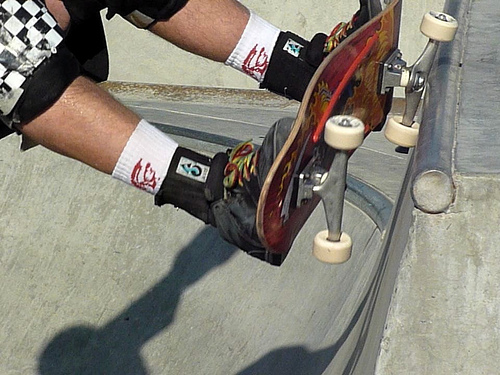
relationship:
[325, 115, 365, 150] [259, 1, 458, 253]
wheel under skateboard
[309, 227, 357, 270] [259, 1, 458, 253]
wheel under skateboard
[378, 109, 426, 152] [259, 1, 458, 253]
wheel under skateboard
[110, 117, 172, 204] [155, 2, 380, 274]
socks on man's feet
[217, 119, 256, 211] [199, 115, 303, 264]
shoelaces on shoe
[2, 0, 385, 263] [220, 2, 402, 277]
man wearing shoes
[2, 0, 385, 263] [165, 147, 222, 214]
man wearing braces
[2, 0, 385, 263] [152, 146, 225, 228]
man wearing ankle brace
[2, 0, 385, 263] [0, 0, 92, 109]
man wearing kneepad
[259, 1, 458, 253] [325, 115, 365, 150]
skateboard with wheel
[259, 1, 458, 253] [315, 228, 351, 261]
skateboard with wheel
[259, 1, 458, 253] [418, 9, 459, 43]
skateboard with wheel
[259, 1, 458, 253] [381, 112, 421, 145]
skateboard with wheel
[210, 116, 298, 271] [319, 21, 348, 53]
shoe with laces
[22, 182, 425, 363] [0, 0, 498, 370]
pavement in skatepark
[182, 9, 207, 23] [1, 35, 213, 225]
hair on leg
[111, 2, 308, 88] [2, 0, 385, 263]
leg on man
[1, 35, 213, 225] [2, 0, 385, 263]
leg on man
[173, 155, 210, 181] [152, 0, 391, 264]
logo on shoes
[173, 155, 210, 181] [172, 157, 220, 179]
logo an arrow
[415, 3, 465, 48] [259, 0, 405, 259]
wheel on skateboard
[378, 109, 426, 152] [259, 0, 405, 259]
wheel on skateboard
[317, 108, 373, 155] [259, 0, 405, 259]
wheel on skateboard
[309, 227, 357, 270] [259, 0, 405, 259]
wheel on skateboard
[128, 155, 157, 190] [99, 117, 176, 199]
design on sock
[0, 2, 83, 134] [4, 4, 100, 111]
kneepad on knee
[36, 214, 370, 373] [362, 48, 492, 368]
shadow on wall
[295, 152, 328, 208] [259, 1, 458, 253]
silver bolt under skateboard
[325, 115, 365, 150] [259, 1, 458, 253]
wheel of skateboard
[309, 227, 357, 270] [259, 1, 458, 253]
wheel of skateboard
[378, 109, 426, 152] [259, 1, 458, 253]
wheel of skateboard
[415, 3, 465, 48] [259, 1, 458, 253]
wheel of skateboard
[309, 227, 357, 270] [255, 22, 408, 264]
wheel of skateboard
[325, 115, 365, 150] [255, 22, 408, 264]
wheel of skateboard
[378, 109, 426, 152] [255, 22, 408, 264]
wheel of skateboard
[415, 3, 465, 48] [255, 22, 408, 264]
wheel of skateboard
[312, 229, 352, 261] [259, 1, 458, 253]
wheel of skateboard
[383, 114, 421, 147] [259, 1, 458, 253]
wheel of skateboard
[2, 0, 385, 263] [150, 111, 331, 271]
man wearing shoes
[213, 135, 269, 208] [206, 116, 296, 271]
lace in shoe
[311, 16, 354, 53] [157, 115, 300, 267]
strings in tennis shoes